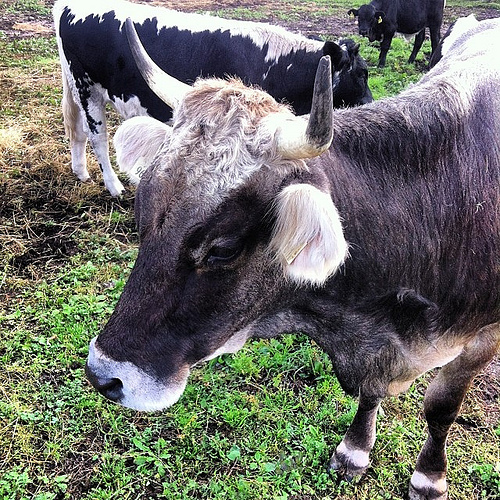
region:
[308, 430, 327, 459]
green grass on the ground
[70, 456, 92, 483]
brown dirt on the ground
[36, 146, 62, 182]
yellow dead grass on ground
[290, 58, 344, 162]
left horn on cow's head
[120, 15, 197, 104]
right horn on cow's head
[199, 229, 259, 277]
the cow's left eye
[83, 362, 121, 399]
nose on the cow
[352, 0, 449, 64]
black cow in the background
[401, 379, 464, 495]
the cow's left front leg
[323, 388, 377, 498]
the cow's right front leg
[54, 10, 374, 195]
black and white spotted cow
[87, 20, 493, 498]
gray and white cow with horns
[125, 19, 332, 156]
horns on the gray and white cow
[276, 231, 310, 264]
tag in the gray cow's left ear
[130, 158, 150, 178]
tag in the gray cow's right ear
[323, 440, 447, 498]
the gray cow's front hoofs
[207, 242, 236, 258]
the gray cow's left eye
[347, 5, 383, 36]
the black cow's head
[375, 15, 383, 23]
yellow tag in the black cow's left ear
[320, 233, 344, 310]
edge of an ear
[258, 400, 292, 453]
part of a ground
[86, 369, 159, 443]
pat of a nose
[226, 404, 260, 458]
part of a ground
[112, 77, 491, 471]
COW STANDING IN GRASS FIELD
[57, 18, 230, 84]
COW STANDING IN GRASS FIELD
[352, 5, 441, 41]
COW STANDING IN GRASS FIELD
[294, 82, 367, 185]
LARGE HORN ON BOVINE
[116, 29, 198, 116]
LARGE HORN ON BOVINE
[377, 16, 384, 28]
YELLOW TAG ON COW'S EAR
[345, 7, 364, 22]
YELLOW TAG ON COW'S EAR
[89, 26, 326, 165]
BLACK SPOTS ON COW'S SKIN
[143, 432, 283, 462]
WEEDS GROWING ON FIELD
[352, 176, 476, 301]
BROWN FUR ON COW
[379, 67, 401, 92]
this is the grass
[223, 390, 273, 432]
the grass is green in color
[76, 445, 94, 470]
this is the ground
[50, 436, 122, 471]
the ground has patches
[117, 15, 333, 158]
these are two horns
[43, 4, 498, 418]
these are some cows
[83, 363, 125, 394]
this is a nose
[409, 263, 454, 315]
the fur is black in color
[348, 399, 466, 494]
these are the feet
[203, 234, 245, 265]
this is an eye